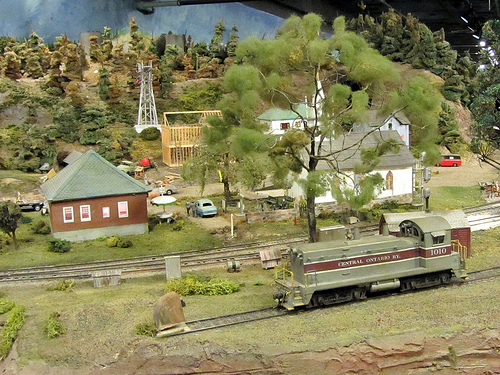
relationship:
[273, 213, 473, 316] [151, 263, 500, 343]
train on spur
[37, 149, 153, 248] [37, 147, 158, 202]
house has roof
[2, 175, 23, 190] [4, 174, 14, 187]
stone has edge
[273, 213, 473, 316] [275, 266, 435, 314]
train has edge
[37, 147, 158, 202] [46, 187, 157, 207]
roof has edge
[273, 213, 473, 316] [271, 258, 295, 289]
train has part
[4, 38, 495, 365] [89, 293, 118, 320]
ground has part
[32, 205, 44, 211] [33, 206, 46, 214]
wheel has part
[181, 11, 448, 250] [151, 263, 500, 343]
oak near spur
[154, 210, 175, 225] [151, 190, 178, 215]
table has umbrella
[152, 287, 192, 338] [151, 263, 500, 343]
stop at end of spur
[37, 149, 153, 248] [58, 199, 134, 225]
house has windows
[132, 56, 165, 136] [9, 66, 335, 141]
tower near hill